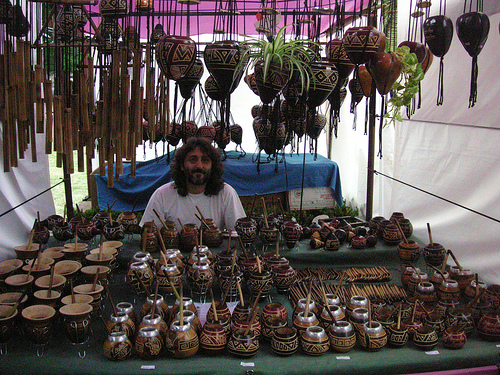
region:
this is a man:
[143, 139, 230, 210]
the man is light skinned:
[182, 153, 199, 160]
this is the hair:
[214, 147, 229, 186]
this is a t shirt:
[161, 192, 186, 218]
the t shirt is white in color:
[198, 197, 228, 208]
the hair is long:
[218, 172, 230, 187]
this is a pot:
[61, 302, 93, 342]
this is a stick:
[300, 281, 314, 313]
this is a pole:
[356, 100, 391, 200]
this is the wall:
[421, 114, 486, 184]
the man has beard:
[174, 144, 219, 191]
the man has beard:
[161, 130, 250, 221]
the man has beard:
[140, 137, 224, 199]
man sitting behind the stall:
[139, 116, 265, 248]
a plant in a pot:
[247, 30, 294, 111]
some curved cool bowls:
[30, 255, 83, 354]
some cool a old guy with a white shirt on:
[161, 138, 242, 211]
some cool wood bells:
[69, 10, 151, 175]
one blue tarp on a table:
[246, 159, 343, 187]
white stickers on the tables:
[266, 350, 480, 370]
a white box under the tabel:
[288, 182, 343, 209]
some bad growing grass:
[53, 165, 90, 204]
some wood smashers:
[325, 265, 394, 296]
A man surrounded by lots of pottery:
[6, 4, 498, 361]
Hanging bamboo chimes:
[4, 33, 159, 183]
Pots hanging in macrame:
[164, 0, 486, 155]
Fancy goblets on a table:
[0, 235, 127, 371]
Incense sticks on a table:
[294, 258, 395, 302]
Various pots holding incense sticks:
[1, 208, 496, 358]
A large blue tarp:
[94, 144, 331, 211]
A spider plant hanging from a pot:
[240, 30, 311, 97]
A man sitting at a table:
[140, 140, 247, 230]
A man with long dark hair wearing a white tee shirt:
[141, 141, 243, 230]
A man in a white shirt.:
[137, 134, 238, 230]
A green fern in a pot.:
[232, 22, 304, 82]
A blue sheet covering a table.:
[97, 143, 341, 208]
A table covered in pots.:
[31, 210, 491, 350]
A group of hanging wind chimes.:
[4, 0, 171, 189]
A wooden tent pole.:
[354, 100, 395, 212]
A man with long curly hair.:
[160, 130, 225, 200]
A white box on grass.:
[287, 186, 338, 212]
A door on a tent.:
[50, 158, 95, 208]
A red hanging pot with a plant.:
[372, 43, 419, 109]